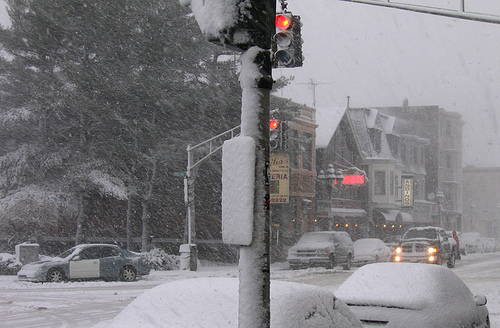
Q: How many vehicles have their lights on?
A: One.